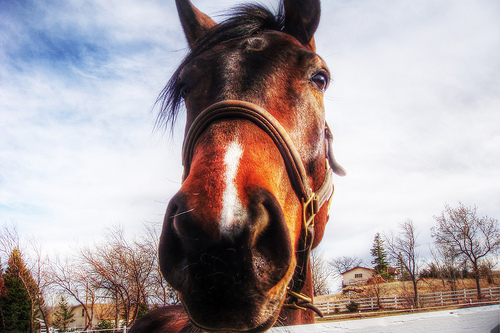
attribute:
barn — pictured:
[47, 305, 134, 328]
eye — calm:
[300, 67, 330, 92]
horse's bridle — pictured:
[177, 94, 335, 255]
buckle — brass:
[254, 153, 353, 249]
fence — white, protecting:
[318, 289, 498, 316]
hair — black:
[159, 2, 277, 124]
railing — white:
[255, 305, 498, 328]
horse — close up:
[110, 1, 362, 332]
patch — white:
[218, 137, 245, 237]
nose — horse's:
[157, 187, 294, 294]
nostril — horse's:
[251, 188, 297, 298]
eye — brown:
[311, 68, 328, 92]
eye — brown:
[173, 86, 190, 103]